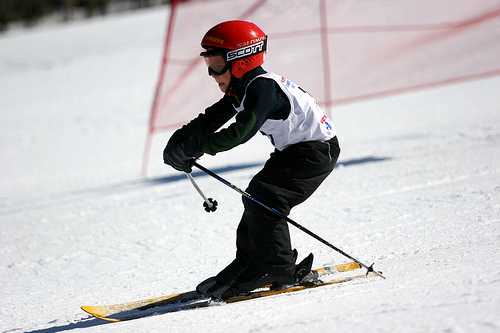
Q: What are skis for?
A: Snow.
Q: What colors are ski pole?
A: Black and blue.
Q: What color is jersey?
A: White.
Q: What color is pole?
A: Black.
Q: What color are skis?
A: Yellow.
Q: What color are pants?
A: Black.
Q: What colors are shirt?
A: Black and white.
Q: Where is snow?
A: On ground.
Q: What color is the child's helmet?
A: Red.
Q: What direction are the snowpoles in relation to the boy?
A: Behind.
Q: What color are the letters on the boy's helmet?
A: Black.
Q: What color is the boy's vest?
A: White.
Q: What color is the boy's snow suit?
A: Black.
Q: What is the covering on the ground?
A: Snow.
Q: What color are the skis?
A: Yellow.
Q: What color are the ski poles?
A: Black.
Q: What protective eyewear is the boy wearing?
A: Goggles.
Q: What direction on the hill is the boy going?
A: Down.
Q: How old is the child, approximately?
A: 10.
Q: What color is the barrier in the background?
A: Red.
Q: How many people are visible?
A: One.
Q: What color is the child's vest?
A: White.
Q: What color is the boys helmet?
A: Red.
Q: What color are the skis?
A: Yellow.